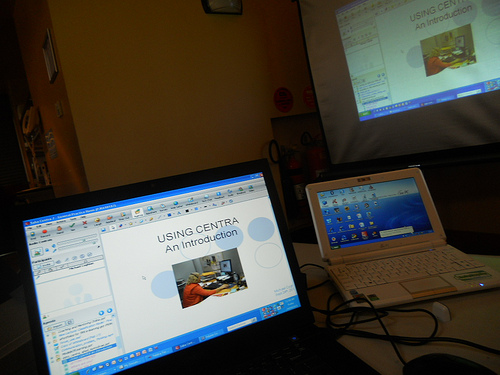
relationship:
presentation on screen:
[333, 1, 500, 118] [294, 2, 498, 172]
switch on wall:
[50, 97, 67, 119] [9, 1, 96, 196]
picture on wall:
[38, 27, 63, 88] [9, 1, 96, 196]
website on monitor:
[31, 181, 296, 373] [7, 155, 314, 372]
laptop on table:
[302, 163, 499, 306] [3, 235, 499, 375]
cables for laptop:
[317, 283, 480, 354] [7, 154, 382, 375]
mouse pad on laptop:
[403, 271, 452, 294] [302, 163, 499, 306]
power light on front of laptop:
[477, 278, 487, 289] [302, 163, 499, 306]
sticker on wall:
[269, 84, 300, 115] [49, 2, 331, 185]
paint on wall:
[35, 4, 37, 8] [9, 1, 96, 196]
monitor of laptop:
[7, 155, 314, 372] [7, 154, 382, 375]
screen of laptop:
[316, 175, 432, 251] [302, 163, 499, 306]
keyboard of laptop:
[326, 245, 480, 292] [302, 163, 499, 306]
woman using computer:
[180, 270, 229, 307] [213, 258, 243, 284]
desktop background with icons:
[319, 181, 427, 235] [322, 184, 388, 244]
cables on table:
[317, 283, 480, 354] [3, 235, 499, 375]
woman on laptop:
[180, 270, 229, 307] [7, 154, 382, 375]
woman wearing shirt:
[180, 270, 229, 307] [180, 282, 218, 310]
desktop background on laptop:
[319, 181, 427, 235] [302, 163, 499, 306]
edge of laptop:
[303, 156, 417, 189] [302, 163, 499, 306]